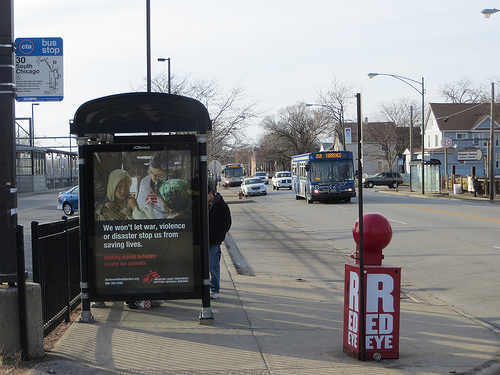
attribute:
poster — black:
[92, 149, 194, 295]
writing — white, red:
[98, 222, 194, 291]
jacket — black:
[204, 189, 242, 245]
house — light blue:
[415, 101, 499, 196]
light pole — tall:
[367, 72, 427, 196]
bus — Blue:
[286, 146, 360, 203]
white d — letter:
[377, 312, 393, 333]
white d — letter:
[111, 232, 115, 239]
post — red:
[343, 212, 401, 362]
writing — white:
[345, 269, 395, 351]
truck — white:
[269, 171, 291, 191]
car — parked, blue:
[51, 181, 98, 216]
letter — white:
[381, 330, 394, 352]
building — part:
[421, 103, 498, 188]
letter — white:
[365, 313, 381, 336]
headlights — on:
[309, 186, 354, 196]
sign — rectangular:
[15, 36, 66, 107]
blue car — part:
[53, 187, 78, 216]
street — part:
[403, 213, 498, 339]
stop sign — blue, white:
[14, 35, 66, 104]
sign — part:
[15, 37, 63, 102]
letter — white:
[348, 269, 419, 361]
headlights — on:
[301, 188, 375, 200]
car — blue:
[57, 183, 78, 214]